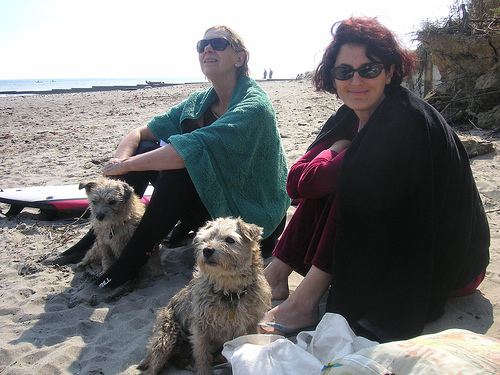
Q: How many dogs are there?
A: Two.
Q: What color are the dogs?
A: Tan.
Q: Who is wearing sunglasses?
A: Two women.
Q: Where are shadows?
A: On the sand.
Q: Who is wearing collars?
A: The dogs.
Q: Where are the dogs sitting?
A: On the sand.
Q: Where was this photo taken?
A: Beach.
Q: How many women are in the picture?
A: Two.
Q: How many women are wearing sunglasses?
A: Two.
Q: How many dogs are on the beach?
A: Two.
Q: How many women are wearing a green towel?
A: One.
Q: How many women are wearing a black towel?
A: One.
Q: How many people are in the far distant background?
A: Two.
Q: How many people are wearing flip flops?
A: One.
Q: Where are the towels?
A: On the women's shoulders.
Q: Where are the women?
A: On the beach.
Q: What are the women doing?
A: Sitting in the sand.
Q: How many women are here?
A: Two.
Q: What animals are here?
A: Dogs.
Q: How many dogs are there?
A: Two.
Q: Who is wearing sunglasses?
A: Both women.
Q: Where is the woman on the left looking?
A: Toward the sky.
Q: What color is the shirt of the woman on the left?
A: Green.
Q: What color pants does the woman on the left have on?
A: Black.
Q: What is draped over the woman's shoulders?
A: A towel.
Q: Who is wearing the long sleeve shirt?
A: Woman on right.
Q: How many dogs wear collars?
A: 2.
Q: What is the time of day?
A: Afternoon.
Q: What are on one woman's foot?
A: Flip flops.